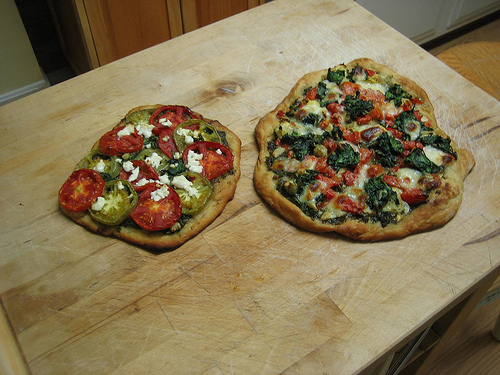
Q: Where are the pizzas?
A: On a wooden table.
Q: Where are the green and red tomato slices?
A: On the left pizza.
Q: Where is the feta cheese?
A: On the left pizza.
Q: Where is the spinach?
A: On the right pizza.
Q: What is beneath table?
A: Floor.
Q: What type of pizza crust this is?
A: Bread crust.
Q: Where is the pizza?
A: On the table.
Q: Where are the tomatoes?
A: Pizza.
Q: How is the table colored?
A: Brown.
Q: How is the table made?
A: Wooden.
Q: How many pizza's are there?
A: Two.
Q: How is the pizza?
A: Spicy.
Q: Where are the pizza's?
A: On the wooden table.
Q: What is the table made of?
A: Wood.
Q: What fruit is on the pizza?
A: Tomatoes.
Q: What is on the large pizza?
A: Vegetables.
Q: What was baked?
A: Pizza.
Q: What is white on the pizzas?
A: Cheese.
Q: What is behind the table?
A: Cabinet.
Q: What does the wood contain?
A: Grains.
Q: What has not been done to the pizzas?
A: Sliced.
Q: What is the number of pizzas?
A: Two.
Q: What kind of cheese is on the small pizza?
A: Feta.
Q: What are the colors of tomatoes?
A: Green and red.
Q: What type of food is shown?
A: Pizza.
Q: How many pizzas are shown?
A: Two.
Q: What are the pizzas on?
A: Table.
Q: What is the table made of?
A: Wood.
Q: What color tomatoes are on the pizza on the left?
A: Green and red.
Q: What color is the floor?
A: Tan.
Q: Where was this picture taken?
A: In a kitchen.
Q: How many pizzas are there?
A: Two.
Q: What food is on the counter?
A: Pizza.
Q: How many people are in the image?
A: None.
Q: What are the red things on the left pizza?
A: Tomatoes.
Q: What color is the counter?
A: Brown.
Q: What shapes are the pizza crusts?
A: Round.